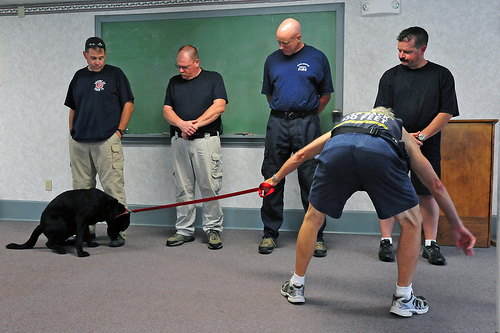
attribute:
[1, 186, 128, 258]
dog — black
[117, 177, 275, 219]
leash — red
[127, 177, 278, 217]
leash — red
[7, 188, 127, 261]
dog — black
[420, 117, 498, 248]
podium — wooden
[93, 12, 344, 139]
chalkboard — green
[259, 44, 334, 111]
tee shirt — blue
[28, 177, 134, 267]
lab — black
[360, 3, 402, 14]
light box — white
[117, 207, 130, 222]
collar — red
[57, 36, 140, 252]
man — white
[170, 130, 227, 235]
pants — dark gray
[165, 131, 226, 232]
pants — light gray